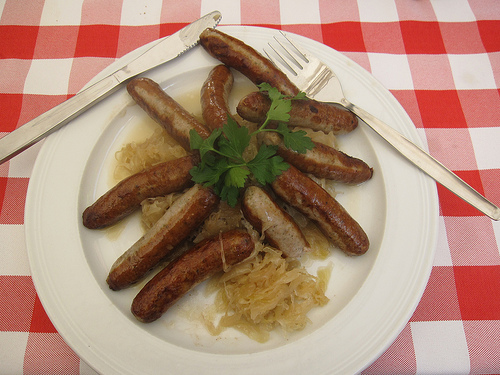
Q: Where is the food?
A: On plate.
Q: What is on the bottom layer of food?
A: Sauerkraut.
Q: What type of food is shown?
A: Sauerkraut and sausage.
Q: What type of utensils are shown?
A: Fork and knife.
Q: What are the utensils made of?
A: Metal.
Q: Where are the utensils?
A: Plate.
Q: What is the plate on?
A: Tablecloth.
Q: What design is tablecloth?
A: Red and white checkered.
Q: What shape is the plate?
A: Round.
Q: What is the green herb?
A: Parsley.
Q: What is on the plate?
A: Sausage and sauerkraut.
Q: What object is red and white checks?
A: Tablecloth.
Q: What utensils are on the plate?
A: Fork and knife.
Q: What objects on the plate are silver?
A: Fork and knife.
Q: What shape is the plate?
A: Round.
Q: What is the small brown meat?
A: Sausage.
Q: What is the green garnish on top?
A: Parsley.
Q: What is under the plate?
A: Tablecloth.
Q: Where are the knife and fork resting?
A: On the plate.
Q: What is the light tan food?
A: Sauerkraut.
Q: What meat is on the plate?
A: Sausages.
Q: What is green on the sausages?
A: Parsley.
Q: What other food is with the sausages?
A: Sauerkraut.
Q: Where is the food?
A: On white plate.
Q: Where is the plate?
A: Tablecloth.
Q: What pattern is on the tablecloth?
A: Red and white checkers.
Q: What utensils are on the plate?
A: Fork and knife.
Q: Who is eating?
A: No one.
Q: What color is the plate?
A: White.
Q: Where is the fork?
A: To the right.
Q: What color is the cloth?
A: Red and white.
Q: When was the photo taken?
A: At a table.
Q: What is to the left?
A: A knife.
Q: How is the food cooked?
A: Fried.